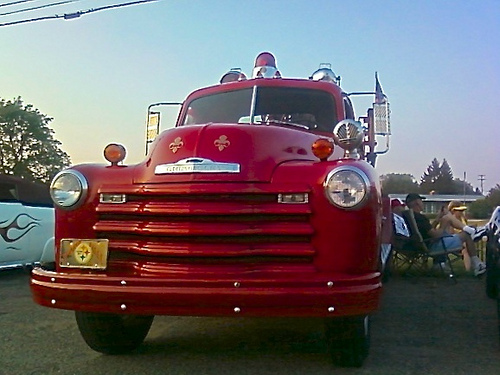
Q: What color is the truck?
A: Red.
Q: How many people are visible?
A: 3.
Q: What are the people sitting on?
A: Chairs.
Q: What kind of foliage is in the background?
A: Trees.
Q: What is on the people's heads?
A: Hats.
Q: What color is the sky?
A: Blue.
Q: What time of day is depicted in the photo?
A: Late afternoon.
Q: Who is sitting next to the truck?
A: People in chairs.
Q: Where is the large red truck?
A: On the ground.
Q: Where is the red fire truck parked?
A: Not on the grass.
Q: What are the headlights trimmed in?
A: Chrome.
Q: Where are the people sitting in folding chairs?
A: Outside by the truck.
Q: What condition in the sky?
A: Bright blue and clear.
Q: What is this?
A: An antique fire truck.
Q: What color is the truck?
A: Red.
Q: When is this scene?
A: Early evening.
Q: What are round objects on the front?
A: Headlights.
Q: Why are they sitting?
A: Spectating.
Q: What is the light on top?
A: Siren.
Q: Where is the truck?
A: In the forefront.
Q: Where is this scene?
A: Near the fire truck.